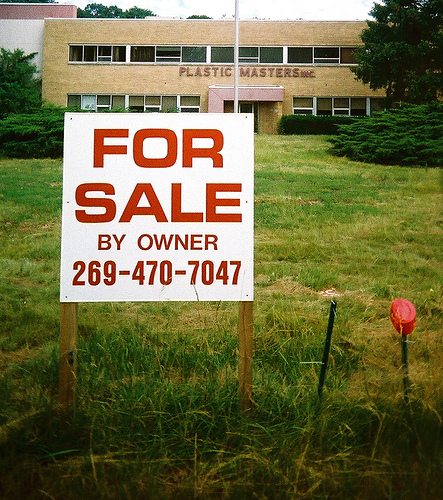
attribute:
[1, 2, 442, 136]
brick building — very large, two-story, tan, concrete, brown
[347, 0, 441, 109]
tree — very large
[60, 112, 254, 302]
sign — white, red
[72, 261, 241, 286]
contact information — red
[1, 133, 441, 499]
lawn — multi-colored, green, hill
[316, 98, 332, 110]
shade — pulled down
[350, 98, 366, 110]
shade — pulled down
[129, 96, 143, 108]
shade — pulled down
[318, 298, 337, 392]
pole — short, black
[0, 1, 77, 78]
building — red, white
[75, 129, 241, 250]
letters — red